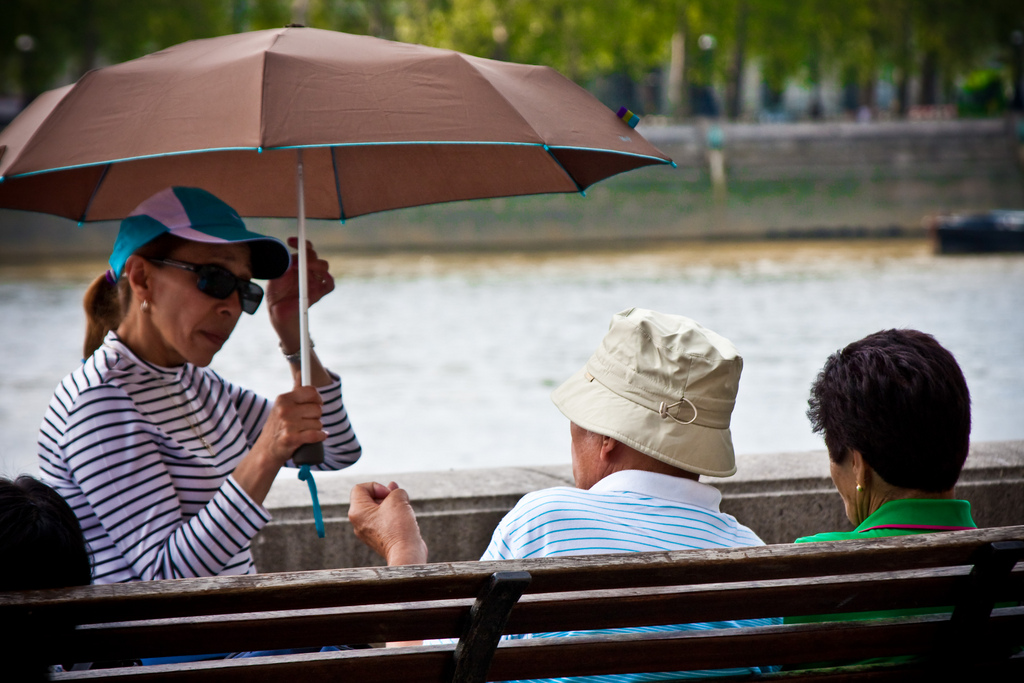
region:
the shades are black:
[182, 263, 263, 315]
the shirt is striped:
[74, 361, 296, 574]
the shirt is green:
[852, 487, 977, 541]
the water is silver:
[362, 257, 1002, 445]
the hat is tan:
[588, 301, 743, 489]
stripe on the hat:
[146, 196, 213, 239]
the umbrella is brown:
[55, 73, 609, 229]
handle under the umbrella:
[286, 156, 344, 485]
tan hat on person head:
[548, 299, 751, 474]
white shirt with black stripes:
[23, 320, 356, 599]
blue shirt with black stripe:
[466, 459, 783, 679]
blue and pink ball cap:
[81, 170, 297, 292]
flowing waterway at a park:
[2, 137, 1021, 518]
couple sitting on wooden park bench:
[6, 290, 1021, 679]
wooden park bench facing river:
[8, 489, 1020, 679]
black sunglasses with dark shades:
[121, 241, 286, 327]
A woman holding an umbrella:
[2, 14, 691, 594]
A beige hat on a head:
[538, 291, 755, 497]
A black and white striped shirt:
[23, 318, 371, 582]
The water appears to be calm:
[0, 219, 1018, 491]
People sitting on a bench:
[2, 168, 1015, 671]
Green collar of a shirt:
[844, 478, 985, 536]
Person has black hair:
[789, 307, 977, 529]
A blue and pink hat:
[92, 162, 301, 289]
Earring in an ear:
[108, 239, 167, 323]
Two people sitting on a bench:
[352, 290, 1019, 680]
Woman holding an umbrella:
[1, 29, 488, 640]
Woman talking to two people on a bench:
[1, 15, 1019, 622]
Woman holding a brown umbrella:
[14, 23, 692, 568]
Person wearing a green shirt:
[782, 315, 1017, 579]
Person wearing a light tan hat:
[332, 296, 781, 645]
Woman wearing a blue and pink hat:
[30, 186, 369, 412]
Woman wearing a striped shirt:
[39, 170, 393, 603]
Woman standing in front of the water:
[11, 19, 484, 671]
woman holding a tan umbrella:
[2, 23, 679, 594]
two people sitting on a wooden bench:
[346, 303, 1020, 667]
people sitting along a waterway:
[4, 206, 1020, 663]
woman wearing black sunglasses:
[78, 181, 293, 375]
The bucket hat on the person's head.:
[561, 304, 736, 482]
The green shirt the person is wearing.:
[802, 502, 987, 627]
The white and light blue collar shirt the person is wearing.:
[479, 471, 773, 640]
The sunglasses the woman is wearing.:
[144, 237, 266, 313]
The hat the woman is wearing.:
[100, 186, 288, 294]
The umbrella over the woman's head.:
[9, 28, 670, 225]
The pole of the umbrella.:
[286, 146, 315, 517]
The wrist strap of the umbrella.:
[302, 458, 323, 539]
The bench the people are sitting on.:
[1, 533, 1023, 677]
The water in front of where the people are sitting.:
[4, 259, 1023, 487]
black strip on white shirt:
[219, 475, 277, 530]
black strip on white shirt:
[210, 478, 264, 539]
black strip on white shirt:
[196, 500, 250, 548]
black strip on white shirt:
[177, 523, 231, 565]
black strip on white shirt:
[161, 536, 191, 576]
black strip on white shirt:
[114, 516, 187, 559]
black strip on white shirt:
[104, 491, 180, 531]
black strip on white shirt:
[95, 472, 171, 510]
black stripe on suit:
[70, 389, 132, 416]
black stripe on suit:
[60, 399, 137, 429]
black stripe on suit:
[68, 432, 144, 464]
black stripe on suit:
[212, 484, 261, 542]